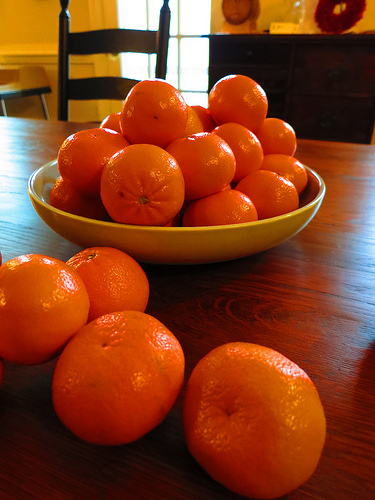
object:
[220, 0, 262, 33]
barrel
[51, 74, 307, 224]
tangerine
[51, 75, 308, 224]
fruit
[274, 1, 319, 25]
glass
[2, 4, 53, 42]
wall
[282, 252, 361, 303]
table top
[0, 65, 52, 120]
chair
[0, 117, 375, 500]
table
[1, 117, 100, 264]
table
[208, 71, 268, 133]
orange fruit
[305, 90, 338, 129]
ground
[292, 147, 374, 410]
table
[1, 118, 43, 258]
light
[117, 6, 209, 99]
window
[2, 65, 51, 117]
table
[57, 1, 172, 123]
chair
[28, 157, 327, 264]
bowl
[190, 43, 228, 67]
ground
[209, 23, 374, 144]
cabinet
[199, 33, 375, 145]
chest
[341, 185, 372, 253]
table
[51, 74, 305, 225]
orange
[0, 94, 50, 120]
legs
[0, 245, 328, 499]
fruit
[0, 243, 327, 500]
orange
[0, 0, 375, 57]
wall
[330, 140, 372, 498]
table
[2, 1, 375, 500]
room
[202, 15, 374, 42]
buffet